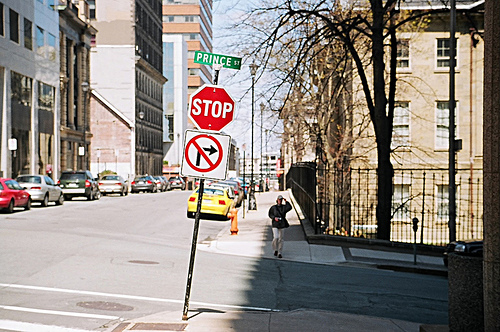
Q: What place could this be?
A: It is a street.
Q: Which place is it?
A: It is a street.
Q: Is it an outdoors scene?
A: Yes, it is outdoors.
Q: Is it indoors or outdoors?
A: It is outdoors.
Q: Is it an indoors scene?
A: No, it is outdoors.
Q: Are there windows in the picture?
A: Yes, there is a window.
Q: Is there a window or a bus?
A: Yes, there is a window.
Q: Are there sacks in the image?
A: No, there are no sacks.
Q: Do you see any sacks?
A: No, there are no sacks.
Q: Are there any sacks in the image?
A: No, there are no sacks.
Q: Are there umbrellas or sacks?
A: No, there are no sacks or umbrellas.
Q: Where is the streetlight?
A: The streetlight is on the sidewalk.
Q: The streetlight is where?
A: The streetlight is on the sidewalk.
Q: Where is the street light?
A: The streetlight is on the sidewalk.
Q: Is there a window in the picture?
A: Yes, there is a window.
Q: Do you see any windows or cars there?
A: Yes, there is a window.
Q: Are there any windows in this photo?
A: Yes, there is a window.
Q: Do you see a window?
A: Yes, there is a window.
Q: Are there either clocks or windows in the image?
A: Yes, there is a window.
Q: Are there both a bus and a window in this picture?
A: No, there is a window but no buses.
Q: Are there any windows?
A: Yes, there is a window.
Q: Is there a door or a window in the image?
A: Yes, there is a window.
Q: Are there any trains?
A: No, there are no trains.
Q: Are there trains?
A: No, there are no trains.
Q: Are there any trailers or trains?
A: No, there are no trains or trailers.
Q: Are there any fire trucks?
A: No, there are no fire trucks.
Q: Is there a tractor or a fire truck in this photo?
A: No, there are no fire trucks or tractors.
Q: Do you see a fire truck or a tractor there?
A: No, there are no fire trucks or tractors.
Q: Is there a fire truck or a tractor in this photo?
A: No, there are no fire trucks or tractors.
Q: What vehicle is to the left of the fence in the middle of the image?
A: The vehicle is a car.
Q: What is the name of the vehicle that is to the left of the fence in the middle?
A: The vehicle is a car.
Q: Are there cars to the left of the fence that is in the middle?
A: Yes, there is a car to the left of the fence.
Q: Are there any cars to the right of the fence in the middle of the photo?
A: No, the car is to the left of the fence.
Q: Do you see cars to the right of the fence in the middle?
A: No, the car is to the left of the fence.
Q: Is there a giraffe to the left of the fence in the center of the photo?
A: No, there is a car to the left of the fence.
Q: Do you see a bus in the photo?
A: No, there are no buses.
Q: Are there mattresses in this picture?
A: No, there are no mattresses.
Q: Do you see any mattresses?
A: No, there are no mattresses.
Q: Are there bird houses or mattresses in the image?
A: No, there are no mattresses or bird houses.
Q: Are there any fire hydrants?
A: Yes, there is a fire hydrant.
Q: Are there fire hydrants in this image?
A: Yes, there is a fire hydrant.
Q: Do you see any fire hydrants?
A: Yes, there is a fire hydrant.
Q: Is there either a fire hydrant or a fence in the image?
A: Yes, there is a fire hydrant.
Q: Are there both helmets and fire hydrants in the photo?
A: No, there is a fire hydrant but no helmets.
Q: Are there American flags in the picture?
A: No, there are no American flags.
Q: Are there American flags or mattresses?
A: No, there are no American flags or mattresses.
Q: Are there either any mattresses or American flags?
A: No, there are no American flags or mattresses.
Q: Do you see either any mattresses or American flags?
A: No, there are no American flags or mattresses.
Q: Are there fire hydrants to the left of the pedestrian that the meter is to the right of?
A: Yes, there is a fire hydrant to the left of the pedestrian.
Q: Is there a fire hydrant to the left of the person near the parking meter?
A: Yes, there is a fire hydrant to the left of the pedestrian.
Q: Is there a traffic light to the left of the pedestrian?
A: No, there is a fire hydrant to the left of the pedestrian.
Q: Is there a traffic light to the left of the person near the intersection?
A: No, there is a fire hydrant to the left of the pedestrian.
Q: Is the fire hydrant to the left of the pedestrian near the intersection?
A: Yes, the fire hydrant is to the left of the pedestrian.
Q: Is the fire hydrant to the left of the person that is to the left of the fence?
A: Yes, the fire hydrant is to the left of the pedestrian.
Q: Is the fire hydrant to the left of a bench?
A: No, the fire hydrant is to the left of the pedestrian.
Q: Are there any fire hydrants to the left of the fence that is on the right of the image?
A: Yes, there is a fire hydrant to the left of the fence.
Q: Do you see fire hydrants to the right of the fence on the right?
A: No, the fire hydrant is to the left of the fence.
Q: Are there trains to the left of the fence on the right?
A: No, there is a fire hydrant to the left of the fence.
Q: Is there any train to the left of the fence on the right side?
A: No, there is a fire hydrant to the left of the fence.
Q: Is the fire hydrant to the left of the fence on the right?
A: Yes, the fire hydrant is to the left of the fence.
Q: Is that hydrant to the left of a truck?
A: No, the hydrant is to the left of the fence.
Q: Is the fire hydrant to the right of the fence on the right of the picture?
A: No, the fire hydrant is to the left of the fence.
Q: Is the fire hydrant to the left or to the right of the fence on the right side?
A: The fire hydrant is to the left of the fence.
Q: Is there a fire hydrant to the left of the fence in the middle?
A: Yes, there is a fire hydrant to the left of the fence.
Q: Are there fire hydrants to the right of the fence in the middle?
A: No, the fire hydrant is to the left of the fence.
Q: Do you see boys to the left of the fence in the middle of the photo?
A: No, there is a fire hydrant to the left of the fence.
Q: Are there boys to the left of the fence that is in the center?
A: No, there is a fire hydrant to the left of the fence.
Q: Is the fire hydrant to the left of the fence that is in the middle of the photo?
A: Yes, the fire hydrant is to the left of the fence.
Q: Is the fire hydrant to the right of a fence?
A: No, the fire hydrant is to the left of a fence.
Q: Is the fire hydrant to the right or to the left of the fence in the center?
A: The fire hydrant is to the left of the fence.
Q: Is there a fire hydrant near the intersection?
A: Yes, there is a fire hydrant near the intersection.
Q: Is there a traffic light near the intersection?
A: No, there is a fire hydrant near the intersection.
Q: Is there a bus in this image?
A: No, there are no buses.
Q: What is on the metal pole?
A: The sign is on the pole.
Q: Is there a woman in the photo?
A: No, there are no women.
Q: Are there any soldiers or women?
A: No, there are no women or soldiers.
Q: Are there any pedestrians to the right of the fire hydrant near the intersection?
A: Yes, there is a pedestrian to the right of the hydrant.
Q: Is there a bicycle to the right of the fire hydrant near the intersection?
A: No, there is a pedestrian to the right of the fire hydrant.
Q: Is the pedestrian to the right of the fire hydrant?
A: Yes, the pedestrian is to the right of the fire hydrant.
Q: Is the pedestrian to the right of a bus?
A: No, the pedestrian is to the right of the fire hydrant.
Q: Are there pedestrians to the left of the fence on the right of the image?
A: Yes, there is a pedestrian to the left of the fence.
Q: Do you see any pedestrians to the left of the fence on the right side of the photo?
A: Yes, there is a pedestrian to the left of the fence.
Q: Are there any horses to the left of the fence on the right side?
A: No, there is a pedestrian to the left of the fence.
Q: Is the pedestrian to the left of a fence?
A: Yes, the pedestrian is to the left of a fence.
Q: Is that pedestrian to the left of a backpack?
A: No, the pedestrian is to the left of a fence.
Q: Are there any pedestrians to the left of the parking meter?
A: Yes, there is a pedestrian to the left of the parking meter.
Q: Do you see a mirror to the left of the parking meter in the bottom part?
A: No, there is a pedestrian to the left of the parking meter.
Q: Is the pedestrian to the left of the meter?
A: Yes, the pedestrian is to the left of the meter.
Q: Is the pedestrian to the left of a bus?
A: No, the pedestrian is to the left of the meter.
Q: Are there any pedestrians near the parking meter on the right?
A: Yes, there is a pedestrian near the parking meter.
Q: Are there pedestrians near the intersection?
A: Yes, there is a pedestrian near the intersection.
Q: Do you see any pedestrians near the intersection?
A: Yes, there is a pedestrian near the intersection.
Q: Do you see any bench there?
A: No, there are no benches.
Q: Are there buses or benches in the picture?
A: No, there are no benches or buses.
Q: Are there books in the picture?
A: No, there are no books.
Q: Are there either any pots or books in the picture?
A: No, there are no books or pots.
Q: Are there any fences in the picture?
A: Yes, there is a fence.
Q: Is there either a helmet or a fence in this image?
A: Yes, there is a fence.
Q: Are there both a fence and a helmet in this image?
A: No, there is a fence but no helmets.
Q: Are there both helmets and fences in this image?
A: No, there is a fence but no helmets.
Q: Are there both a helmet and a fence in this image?
A: No, there is a fence but no helmets.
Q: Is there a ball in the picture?
A: No, there are no balls.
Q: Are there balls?
A: No, there are no balls.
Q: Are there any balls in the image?
A: No, there are no balls.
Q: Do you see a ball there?
A: No, there are no balls.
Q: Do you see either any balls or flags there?
A: No, there are no balls or flags.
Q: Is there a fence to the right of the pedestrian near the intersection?
A: Yes, there is a fence to the right of the pedestrian.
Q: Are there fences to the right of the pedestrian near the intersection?
A: Yes, there is a fence to the right of the pedestrian.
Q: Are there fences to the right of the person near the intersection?
A: Yes, there is a fence to the right of the pedestrian.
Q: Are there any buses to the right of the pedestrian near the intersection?
A: No, there is a fence to the right of the pedestrian.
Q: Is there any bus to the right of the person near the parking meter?
A: No, there is a fence to the right of the pedestrian.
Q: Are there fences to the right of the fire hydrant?
A: Yes, there is a fence to the right of the fire hydrant.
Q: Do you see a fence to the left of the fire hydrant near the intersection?
A: No, the fence is to the right of the fire hydrant.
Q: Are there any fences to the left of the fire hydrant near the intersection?
A: No, the fence is to the right of the fire hydrant.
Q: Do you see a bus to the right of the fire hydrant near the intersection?
A: No, there is a fence to the right of the hydrant.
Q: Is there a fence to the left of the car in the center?
A: No, the fence is to the right of the car.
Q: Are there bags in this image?
A: No, there are no bags.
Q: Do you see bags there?
A: No, there are no bags.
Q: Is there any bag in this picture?
A: No, there are no bags.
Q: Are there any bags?
A: No, there are no bags.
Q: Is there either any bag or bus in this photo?
A: No, there are no bags or buses.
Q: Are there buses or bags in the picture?
A: No, there are no buses or bags.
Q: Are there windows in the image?
A: Yes, there is a window.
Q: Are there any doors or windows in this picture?
A: Yes, there is a window.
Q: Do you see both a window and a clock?
A: No, there is a window but no clocks.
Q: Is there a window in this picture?
A: Yes, there is a window.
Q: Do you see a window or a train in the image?
A: Yes, there is a window.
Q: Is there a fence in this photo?
A: Yes, there is a fence.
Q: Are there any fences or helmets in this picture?
A: Yes, there is a fence.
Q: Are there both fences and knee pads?
A: No, there is a fence but no knee pads.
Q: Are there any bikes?
A: No, there are no bikes.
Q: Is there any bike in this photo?
A: No, there are no bikes.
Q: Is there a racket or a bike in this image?
A: No, there are no bikes or rackets.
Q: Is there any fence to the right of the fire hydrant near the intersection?
A: Yes, there is a fence to the right of the hydrant.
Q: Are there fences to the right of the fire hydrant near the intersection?
A: Yes, there is a fence to the right of the hydrant.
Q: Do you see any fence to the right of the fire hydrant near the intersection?
A: Yes, there is a fence to the right of the hydrant.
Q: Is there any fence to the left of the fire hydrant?
A: No, the fence is to the right of the fire hydrant.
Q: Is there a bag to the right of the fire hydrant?
A: No, there is a fence to the right of the fire hydrant.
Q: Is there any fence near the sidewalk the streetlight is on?
A: Yes, there is a fence near the sidewalk.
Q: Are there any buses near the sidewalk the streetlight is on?
A: No, there is a fence near the side walk.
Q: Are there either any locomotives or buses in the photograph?
A: No, there are no buses or locomotives.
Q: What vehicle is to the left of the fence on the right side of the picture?
A: The vehicle is a car.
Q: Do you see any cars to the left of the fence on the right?
A: Yes, there is a car to the left of the fence.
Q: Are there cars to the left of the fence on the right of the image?
A: Yes, there is a car to the left of the fence.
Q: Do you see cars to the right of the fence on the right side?
A: No, the car is to the left of the fence.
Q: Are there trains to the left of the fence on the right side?
A: No, there is a car to the left of the fence.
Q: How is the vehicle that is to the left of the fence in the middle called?
A: The vehicle is a car.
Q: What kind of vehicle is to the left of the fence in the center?
A: The vehicle is a car.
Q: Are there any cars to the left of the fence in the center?
A: Yes, there is a car to the left of the fence.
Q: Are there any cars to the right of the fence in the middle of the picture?
A: No, the car is to the left of the fence.